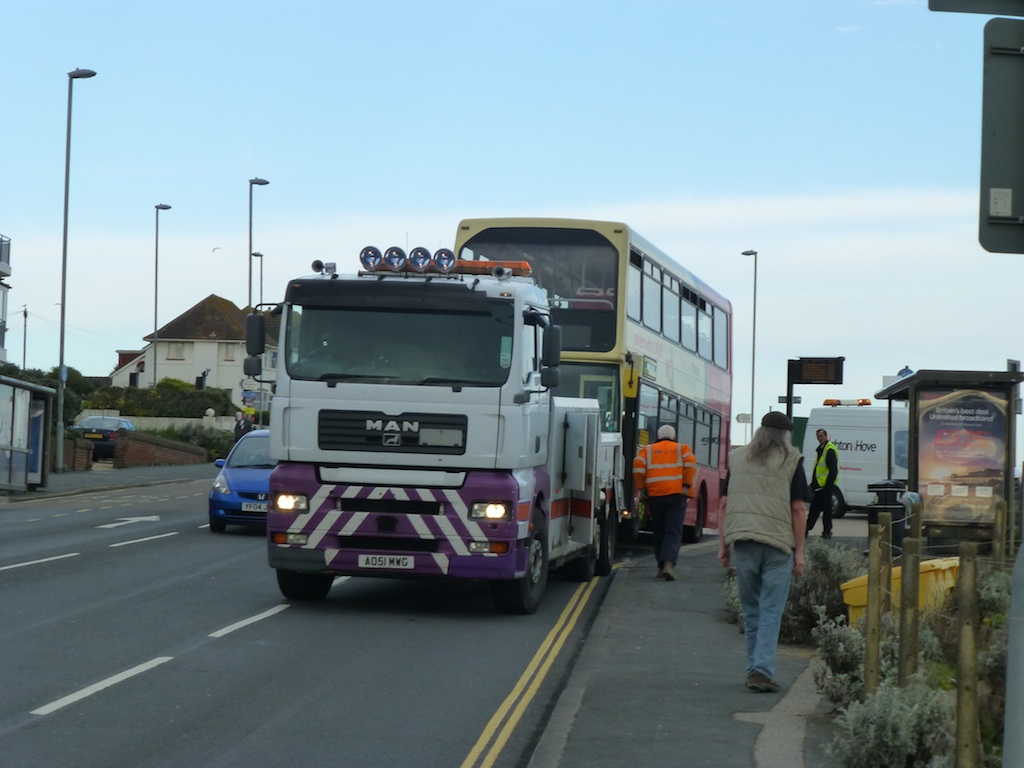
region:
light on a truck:
[434, 479, 511, 546]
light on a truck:
[258, 481, 313, 533]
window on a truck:
[285, 302, 513, 379]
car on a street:
[193, 424, 263, 535]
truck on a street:
[266, 258, 568, 610]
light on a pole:
[43, 49, 113, 133]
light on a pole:
[136, 177, 175, 245]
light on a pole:
[712, 212, 789, 269]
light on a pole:
[219, 155, 300, 225]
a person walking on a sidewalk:
[739, 382, 813, 686]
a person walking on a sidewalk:
[644, 391, 693, 573]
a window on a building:
[153, 334, 201, 374]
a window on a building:
[220, 339, 249, 369]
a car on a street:
[207, 421, 287, 530]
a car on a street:
[809, 394, 926, 527]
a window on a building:
[240, 382, 275, 420]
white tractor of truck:
[250, 242, 612, 607]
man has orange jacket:
[620, 435, 678, 512]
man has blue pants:
[652, 501, 692, 575]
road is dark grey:
[317, 605, 407, 761]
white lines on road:
[1, 556, 331, 760]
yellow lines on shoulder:
[452, 618, 579, 765]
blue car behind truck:
[218, 407, 302, 573]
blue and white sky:
[681, 63, 985, 373]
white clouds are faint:
[718, 144, 871, 347]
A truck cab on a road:
[257, 266, 612, 598]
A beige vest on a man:
[721, 439, 798, 553]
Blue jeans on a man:
[728, 531, 787, 681]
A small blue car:
[201, 417, 281, 529]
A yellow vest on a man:
[806, 440, 838, 479]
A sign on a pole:
[776, 356, 852, 383]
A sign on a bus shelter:
[908, 388, 1010, 515]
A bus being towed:
[460, 211, 735, 502]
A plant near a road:
[822, 679, 956, 762]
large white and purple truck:
[271, 228, 608, 618]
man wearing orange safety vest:
[632, 410, 713, 584]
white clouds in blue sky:
[180, 54, 234, 111]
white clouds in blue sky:
[694, 199, 727, 242]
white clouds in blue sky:
[91, 249, 133, 316]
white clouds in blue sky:
[228, 81, 279, 119]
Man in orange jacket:
[597, 421, 708, 573]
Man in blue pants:
[622, 413, 700, 581]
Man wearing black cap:
[702, 402, 836, 700]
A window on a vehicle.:
[272, 292, 519, 404]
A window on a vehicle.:
[445, 235, 610, 299]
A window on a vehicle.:
[534, 296, 602, 339]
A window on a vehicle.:
[613, 266, 643, 321]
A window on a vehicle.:
[635, 276, 659, 333]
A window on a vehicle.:
[678, 307, 698, 347]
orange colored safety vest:
[622, 433, 706, 503]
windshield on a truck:
[287, 297, 512, 397]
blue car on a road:
[202, 418, 288, 539]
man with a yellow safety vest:
[808, 418, 848, 548]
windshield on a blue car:
[224, 429, 279, 471]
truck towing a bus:
[249, 243, 624, 613]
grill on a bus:
[310, 407, 472, 462]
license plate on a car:
[240, 497, 270, 516]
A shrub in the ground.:
[847, 683, 956, 760]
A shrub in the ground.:
[812, 614, 895, 701]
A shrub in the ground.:
[780, 547, 860, 642]